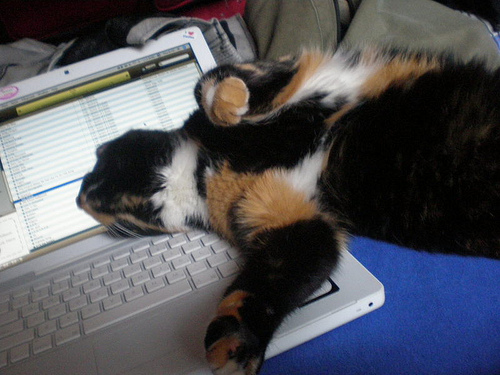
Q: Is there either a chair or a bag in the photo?
A: No, there are no chairs or bags.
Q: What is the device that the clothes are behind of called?
A: The device is a laptop.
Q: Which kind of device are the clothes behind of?
A: The clothes are behind the laptop computer.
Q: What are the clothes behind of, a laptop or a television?
A: The clothes are behind a laptop.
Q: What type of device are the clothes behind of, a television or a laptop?
A: The clothes are behind a laptop.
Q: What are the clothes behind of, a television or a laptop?
A: The clothes are behind a laptop.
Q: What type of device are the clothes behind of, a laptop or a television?
A: The clothes are behind a laptop.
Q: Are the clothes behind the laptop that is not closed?
A: Yes, the clothes are behind the laptop.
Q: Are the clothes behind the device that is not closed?
A: Yes, the clothes are behind the laptop.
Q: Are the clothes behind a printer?
A: No, the clothes are behind the laptop.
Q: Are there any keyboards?
A: Yes, there is a keyboard.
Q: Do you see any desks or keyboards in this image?
A: Yes, there is a keyboard.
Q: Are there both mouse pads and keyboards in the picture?
A: No, there is a keyboard but no mouse pads.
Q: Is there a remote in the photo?
A: No, there are no remote controls.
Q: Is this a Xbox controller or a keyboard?
A: This is a keyboard.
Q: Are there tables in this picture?
A: Yes, there is a table.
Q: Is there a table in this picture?
A: Yes, there is a table.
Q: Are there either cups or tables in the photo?
A: Yes, there is a table.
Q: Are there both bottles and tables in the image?
A: No, there is a table but no bottles.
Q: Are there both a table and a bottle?
A: No, there is a table but no bottles.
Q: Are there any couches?
A: No, there are no couches.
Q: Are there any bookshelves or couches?
A: No, there are no couches or bookshelves.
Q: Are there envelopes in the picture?
A: No, there are no envelopes.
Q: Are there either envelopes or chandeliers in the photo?
A: No, there are no envelopes or chandeliers.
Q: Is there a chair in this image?
A: No, there are no chairs.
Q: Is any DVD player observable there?
A: No, there are no DVD players.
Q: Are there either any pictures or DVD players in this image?
A: No, there are no DVD players or pictures.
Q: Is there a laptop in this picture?
A: Yes, there is a laptop.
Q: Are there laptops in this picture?
A: Yes, there is a laptop.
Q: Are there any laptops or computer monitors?
A: Yes, there is a laptop.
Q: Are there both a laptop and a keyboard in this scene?
A: Yes, there are both a laptop and a keyboard.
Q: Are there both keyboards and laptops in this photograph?
A: Yes, there are both a laptop and a keyboard.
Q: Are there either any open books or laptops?
A: Yes, there is an open laptop.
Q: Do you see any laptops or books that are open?
A: Yes, the laptop is open.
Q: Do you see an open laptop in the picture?
A: Yes, there is an open laptop.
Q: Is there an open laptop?
A: Yes, there is an open laptop.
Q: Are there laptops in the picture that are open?
A: Yes, there is a laptop that is open.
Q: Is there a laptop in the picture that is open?
A: Yes, there is a laptop that is open.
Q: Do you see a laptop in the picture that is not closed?
A: Yes, there is a open laptop.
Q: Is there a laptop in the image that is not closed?
A: Yes, there is a open laptop.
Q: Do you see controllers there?
A: No, there are no controllers.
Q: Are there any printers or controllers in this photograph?
A: No, there are no controllers or printers.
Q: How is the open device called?
A: The device is a laptop.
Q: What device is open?
A: The device is a laptop.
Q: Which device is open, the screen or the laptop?
A: The laptop is open.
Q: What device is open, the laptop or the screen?
A: The laptop is open.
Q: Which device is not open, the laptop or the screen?
A: The screen is not open.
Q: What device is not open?
A: The device is a screen.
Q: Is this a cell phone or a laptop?
A: This is a laptop.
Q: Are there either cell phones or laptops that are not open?
A: No, there is a laptop but it is open.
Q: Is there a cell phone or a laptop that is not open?
A: No, there is a laptop but it is open.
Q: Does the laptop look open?
A: Yes, the laptop is open.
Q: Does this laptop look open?
A: Yes, the laptop is open.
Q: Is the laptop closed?
A: No, the laptop is open.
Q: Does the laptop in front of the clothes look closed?
A: No, the laptop computer is open.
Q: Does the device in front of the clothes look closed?
A: No, the laptop computer is open.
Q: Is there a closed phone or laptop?
A: No, there is a laptop but it is open.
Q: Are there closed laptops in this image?
A: No, there is a laptop but it is open.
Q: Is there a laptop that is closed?
A: No, there is a laptop but it is open.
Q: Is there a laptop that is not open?
A: No, there is a laptop but it is open.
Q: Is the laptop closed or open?
A: The laptop is open.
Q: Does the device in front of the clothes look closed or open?
A: The laptop is open.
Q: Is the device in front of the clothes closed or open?
A: The laptop is open.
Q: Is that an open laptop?
A: Yes, that is an open laptop.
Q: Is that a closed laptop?
A: No, that is an open laptop.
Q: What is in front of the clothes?
A: The laptop computer is in front of the clothes.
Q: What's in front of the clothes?
A: The laptop computer is in front of the clothes.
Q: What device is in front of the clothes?
A: The device is a laptop.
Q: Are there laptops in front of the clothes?
A: Yes, there is a laptop in front of the clothes.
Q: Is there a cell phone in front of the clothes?
A: No, there is a laptop in front of the clothes.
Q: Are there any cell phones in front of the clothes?
A: No, there is a laptop in front of the clothes.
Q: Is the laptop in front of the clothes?
A: Yes, the laptop is in front of the clothes.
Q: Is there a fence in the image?
A: No, there are no fences.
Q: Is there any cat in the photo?
A: Yes, there is a cat.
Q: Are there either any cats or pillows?
A: Yes, there is a cat.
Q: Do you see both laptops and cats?
A: Yes, there are both a cat and a laptop.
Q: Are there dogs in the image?
A: No, there are no dogs.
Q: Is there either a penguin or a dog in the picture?
A: No, there are no dogs or penguins.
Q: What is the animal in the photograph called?
A: The animal is a cat.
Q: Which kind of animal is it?
A: The animal is a cat.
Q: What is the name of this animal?
A: This is a cat.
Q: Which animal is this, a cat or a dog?
A: This is a cat.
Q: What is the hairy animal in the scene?
A: The animal is a cat.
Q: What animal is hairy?
A: The animal is a cat.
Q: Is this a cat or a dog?
A: This is a cat.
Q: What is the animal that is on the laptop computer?
A: The animal is a cat.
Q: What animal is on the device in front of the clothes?
A: The animal is a cat.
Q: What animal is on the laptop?
A: The animal is a cat.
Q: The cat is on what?
A: The cat is on the laptop computer.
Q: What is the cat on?
A: The cat is on the laptop computer.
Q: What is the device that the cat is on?
A: The device is a laptop.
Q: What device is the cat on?
A: The cat is on the laptop.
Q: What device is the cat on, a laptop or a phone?
A: The cat is on a laptop.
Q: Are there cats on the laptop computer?
A: Yes, there is a cat on the laptop computer.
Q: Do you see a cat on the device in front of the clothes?
A: Yes, there is a cat on the laptop computer.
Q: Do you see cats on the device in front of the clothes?
A: Yes, there is a cat on the laptop computer.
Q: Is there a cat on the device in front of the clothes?
A: Yes, there is a cat on the laptop computer.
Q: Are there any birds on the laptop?
A: No, there is a cat on the laptop.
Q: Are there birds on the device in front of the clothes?
A: No, there is a cat on the laptop.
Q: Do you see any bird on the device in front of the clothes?
A: No, there is a cat on the laptop.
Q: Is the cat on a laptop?
A: Yes, the cat is on a laptop.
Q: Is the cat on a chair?
A: No, the cat is on a laptop.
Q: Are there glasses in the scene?
A: No, there are no glasses.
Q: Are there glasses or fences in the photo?
A: No, there are no glasses or fences.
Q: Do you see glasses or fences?
A: No, there are no glasses or fences.